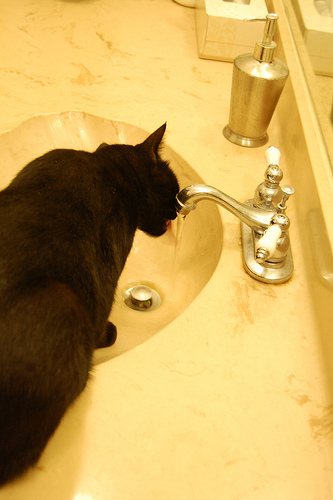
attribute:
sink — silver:
[16, 105, 250, 342]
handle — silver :
[249, 140, 282, 190]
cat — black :
[7, 96, 176, 499]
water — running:
[176, 213, 202, 254]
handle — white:
[258, 140, 286, 169]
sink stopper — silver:
[124, 283, 163, 312]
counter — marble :
[11, 12, 177, 100]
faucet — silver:
[176, 183, 275, 234]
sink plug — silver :
[127, 284, 159, 314]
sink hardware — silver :
[172, 143, 295, 288]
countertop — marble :
[0, 0, 332, 498]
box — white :
[194, 0, 269, 63]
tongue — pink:
[167, 218, 185, 235]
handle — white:
[255, 220, 284, 262]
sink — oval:
[2, 108, 223, 364]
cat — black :
[0, 120, 181, 487]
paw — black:
[91, 316, 119, 347]